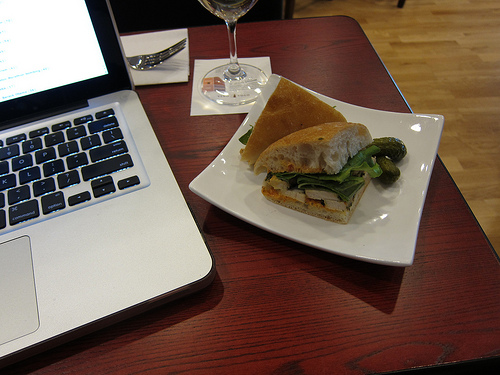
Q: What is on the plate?
A: A sandwich.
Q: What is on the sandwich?
A: Lettuce and chicken.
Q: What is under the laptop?
A: A dark desk.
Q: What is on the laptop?
A: A keyboard.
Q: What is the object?
A: A wooden deck top.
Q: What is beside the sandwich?
A: A green pickle.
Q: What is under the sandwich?
A: A white plate.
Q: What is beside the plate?
A: A glass.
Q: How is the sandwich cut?
A: In triangles.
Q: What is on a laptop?
A: Keyboard.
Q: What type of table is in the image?
A: Wooden.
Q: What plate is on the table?
A: Ceramic.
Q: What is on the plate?
A: Mushroom and lettuce on ciabatta bread.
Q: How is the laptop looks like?
A: Good.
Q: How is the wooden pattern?
A: Light wood.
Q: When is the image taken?
A: Food is on plate.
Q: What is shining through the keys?
A: Blue light.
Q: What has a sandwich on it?
A: Plate.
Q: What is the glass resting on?
A: Napkin.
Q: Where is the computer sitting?
A: Desk.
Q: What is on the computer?
A: Keys.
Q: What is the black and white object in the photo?
A: Laptop.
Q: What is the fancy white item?
A: Plate.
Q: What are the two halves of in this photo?
A: Sandwich.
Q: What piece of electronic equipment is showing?
A: A laptop.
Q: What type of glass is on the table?
A: A wine glass.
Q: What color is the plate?
A: White.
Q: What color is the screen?
A: White.